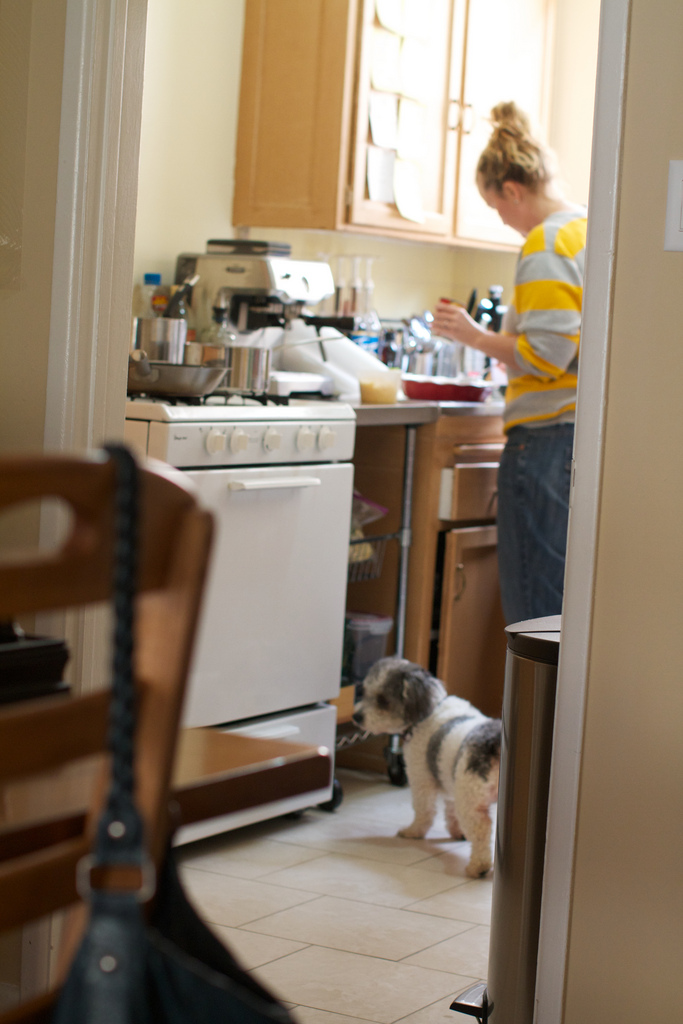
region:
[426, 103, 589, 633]
a woman cooking in a kitchen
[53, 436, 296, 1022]
a blurry black purse on a chair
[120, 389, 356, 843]
white stove and oven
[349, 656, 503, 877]
a furry little white and gray dog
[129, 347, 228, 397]
a saute pan on a stove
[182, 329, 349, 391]
a pot on a stove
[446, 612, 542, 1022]
a garbage can in a kitchen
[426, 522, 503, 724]
an open cabinet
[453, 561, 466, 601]
a handle on a kitchen cabinet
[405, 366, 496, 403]
a red baking dish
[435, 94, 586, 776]
woman standing at counter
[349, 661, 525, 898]
dog next to woman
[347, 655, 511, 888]
dog in kitchen is small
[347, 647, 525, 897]
dog is black and white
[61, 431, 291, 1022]
purse hanging on chair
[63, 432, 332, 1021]
purse on chair is black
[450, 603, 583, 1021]
garbage can in kitchen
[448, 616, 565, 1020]
garbage can is silver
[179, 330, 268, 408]
pot on top of stove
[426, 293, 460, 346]
woman holding spices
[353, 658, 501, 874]
small grey and white dog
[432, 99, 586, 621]
woman wearing blue jeans and striped shirt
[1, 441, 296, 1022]
black purse hanging on wooden chair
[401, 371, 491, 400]
short round red dish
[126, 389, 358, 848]
white stove with five knobs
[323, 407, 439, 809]
metal wire cart with black wheels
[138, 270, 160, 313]
clear bottle with blue cap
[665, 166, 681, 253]
white light switch plate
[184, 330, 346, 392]
shiny silver pot with long handle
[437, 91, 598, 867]
Woman standing wearing a yellow and gray striped sweater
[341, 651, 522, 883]
Small black and white dog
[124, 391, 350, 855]
Closed white oven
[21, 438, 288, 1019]
Black purse hanging on the back of a chair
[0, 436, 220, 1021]
Wooden chair tucked under table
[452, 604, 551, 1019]
Silver trash can with black pedal and lid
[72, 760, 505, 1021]
Tiled flooring in a kitchen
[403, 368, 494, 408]
Red pan sitting on counter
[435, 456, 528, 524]
Partially open drawer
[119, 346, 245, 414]
Silver metal bowl sitting on top of oven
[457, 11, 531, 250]
a door for a cabinet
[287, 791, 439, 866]
a tile in a floor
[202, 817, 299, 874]
a tile in a floor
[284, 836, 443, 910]
a tile in a floor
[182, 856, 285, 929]
a tile in a floor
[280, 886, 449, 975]
a tile in a floor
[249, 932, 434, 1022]
a tile in a floor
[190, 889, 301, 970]
a tile in a floor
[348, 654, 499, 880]
a small gray and white dog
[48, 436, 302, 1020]
a purse with a long black strap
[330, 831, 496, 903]
shadow of the dog on the floor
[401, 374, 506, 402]
a skillet with a red exterior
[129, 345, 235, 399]
a silver pan on the stove